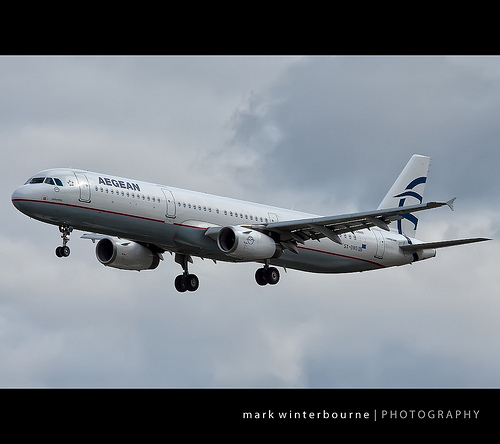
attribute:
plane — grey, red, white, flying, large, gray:
[9, 143, 493, 304]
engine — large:
[87, 235, 164, 279]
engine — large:
[211, 222, 286, 269]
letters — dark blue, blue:
[95, 171, 143, 195]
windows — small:
[92, 185, 163, 204]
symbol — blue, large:
[397, 172, 427, 238]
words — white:
[231, 400, 484, 428]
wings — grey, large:
[263, 196, 457, 244]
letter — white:
[253, 410, 262, 422]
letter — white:
[323, 406, 330, 422]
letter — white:
[308, 408, 315, 422]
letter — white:
[427, 407, 435, 422]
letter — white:
[389, 409, 399, 422]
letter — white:
[288, 408, 294, 423]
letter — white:
[243, 408, 253, 421]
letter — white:
[267, 407, 276, 419]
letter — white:
[261, 411, 267, 421]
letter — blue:
[134, 181, 142, 195]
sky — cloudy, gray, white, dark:
[3, 56, 291, 167]